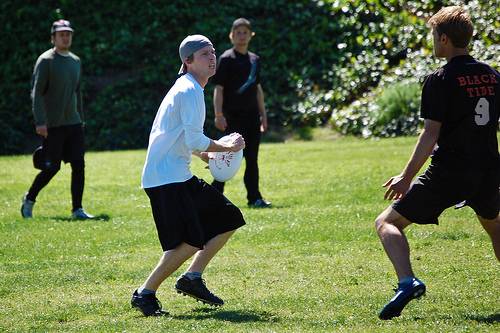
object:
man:
[127, 33, 248, 318]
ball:
[210, 137, 244, 183]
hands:
[201, 133, 246, 164]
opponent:
[373, 7, 499, 321]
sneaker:
[173, 274, 226, 308]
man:
[20, 18, 96, 219]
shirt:
[32, 48, 88, 126]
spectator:
[212, 17, 269, 206]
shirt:
[212, 49, 262, 121]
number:
[474, 97, 489, 128]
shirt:
[419, 56, 499, 169]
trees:
[0, 2, 499, 153]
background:
[0, 0, 499, 169]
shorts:
[143, 175, 246, 251]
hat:
[177, 33, 215, 77]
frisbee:
[207, 137, 242, 183]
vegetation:
[1, 1, 498, 148]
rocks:
[75, 60, 141, 106]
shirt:
[140, 75, 212, 189]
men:
[20, 6, 498, 322]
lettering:
[457, 72, 498, 97]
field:
[0, 128, 496, 333]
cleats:
[130, 274, 223, 315]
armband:
[215, 112, 224, 117]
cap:
[32, 136, 50, 173]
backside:
[140, 72, 183, 194]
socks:
[138, 272, 203, 294]